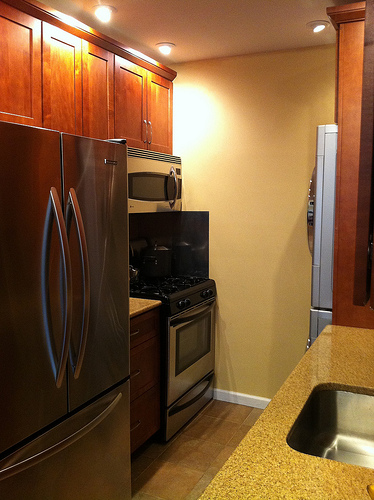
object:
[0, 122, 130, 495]
refrigerator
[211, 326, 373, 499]
counter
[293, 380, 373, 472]
sink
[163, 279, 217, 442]
oven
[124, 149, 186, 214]
microwave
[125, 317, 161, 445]
drawers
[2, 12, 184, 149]
cabinets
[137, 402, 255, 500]
floor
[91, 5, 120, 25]
light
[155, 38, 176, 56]
light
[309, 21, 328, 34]
light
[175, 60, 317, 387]
wall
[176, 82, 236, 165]
light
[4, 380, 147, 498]
freezer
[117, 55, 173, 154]
cupboard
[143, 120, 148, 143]
handles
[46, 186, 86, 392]
handles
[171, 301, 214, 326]
handle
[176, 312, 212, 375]
window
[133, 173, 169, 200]
window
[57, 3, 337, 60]
ceiling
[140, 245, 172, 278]
pot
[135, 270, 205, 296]
stove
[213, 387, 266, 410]
baseboard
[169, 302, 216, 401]
door